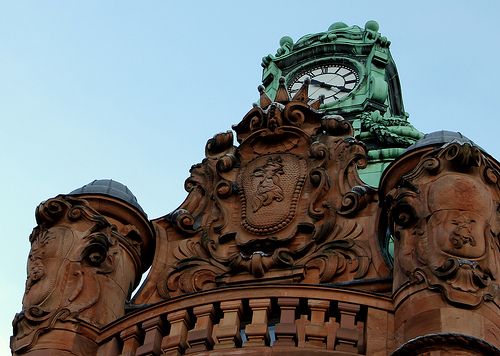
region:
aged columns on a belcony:
[157, 291, 372, 354]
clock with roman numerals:
[282, 50, 366, 110]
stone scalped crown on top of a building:
[252, 77, 338, 120]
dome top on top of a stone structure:
[51, 169, 163, 249]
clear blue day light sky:
[52, 22, 188, 144]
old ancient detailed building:
[18, 92, 481, 345]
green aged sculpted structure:
[248, 17, 393, 61]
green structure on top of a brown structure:
[244, 36, 406, 197]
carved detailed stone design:
[173, 208, 243, 284]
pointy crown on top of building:
[234, 76, 355, 179]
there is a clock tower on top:
[248, 18, 422, 151]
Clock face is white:
[272, 53, 363, 108]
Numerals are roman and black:
[286, 56, 361, 108]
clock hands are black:
[288, 58, 359, 108]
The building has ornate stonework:
[15, 83, 499, 355]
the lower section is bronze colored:
[14, 81, 498, 354]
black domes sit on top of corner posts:
[57, 126, 497, 224]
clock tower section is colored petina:
[248, 16, 430, 266]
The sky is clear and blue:
[1, 1, 499, 348]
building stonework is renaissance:
[11, 17, 498, 350]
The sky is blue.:
[2, 2, 494, 192]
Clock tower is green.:
[252, 19, 419, 154]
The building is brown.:
[15, 95, 494, 352]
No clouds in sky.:
[4, 2, 198, 207]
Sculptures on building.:
[162, 86, 383, 288]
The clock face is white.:
[286, 61, 360, 111]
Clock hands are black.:
[282, 57, 362, 108]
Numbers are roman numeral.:
[282, 53, 363, 110]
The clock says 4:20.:
[285, 54, 366, 116]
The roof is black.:
[55, 166, 150, 236]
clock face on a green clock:
[274, 50, 367, 112]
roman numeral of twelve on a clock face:
[319, 62, 331, 77]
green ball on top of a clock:
[363, 16, 380, 33]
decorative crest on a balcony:
[236, 146, 312, 238]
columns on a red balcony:
[100, 285, 394, 355]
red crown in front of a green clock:
[250, 77, 326, 112]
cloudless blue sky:
[5, 3, 207, 79]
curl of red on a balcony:
[168, 208, 200, 231]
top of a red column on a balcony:
[59, 171, 151, 211]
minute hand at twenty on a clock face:
[325, 78, 356, 99]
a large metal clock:
[276, 51, 373, 116]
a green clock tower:
[241, 16, 433, 191]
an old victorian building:
[12, 14, 499, 353]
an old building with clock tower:
[9, 9, 490, 351]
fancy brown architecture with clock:
[11, 99, 498, 351]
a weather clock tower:
[220, 15, 443, 181]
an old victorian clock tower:
[6, 12, 495, 346]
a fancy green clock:
[246, 16, 448, 184]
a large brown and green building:
[15, 12, 495, 354]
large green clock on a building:
[204, 13, 443, 203]